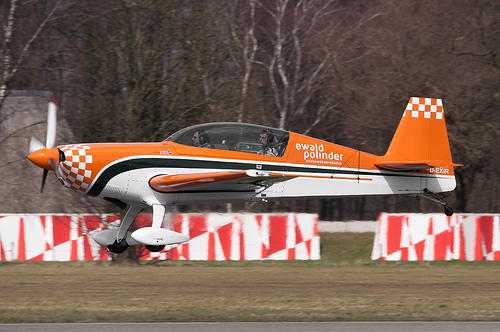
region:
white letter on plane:
[292, 141, 304, 151]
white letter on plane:
[301, 142, 308, 150]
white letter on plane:
[309, 144, 315, 151]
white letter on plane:
[313, 142, 319, 150]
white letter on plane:
[301, 148, 310, 160]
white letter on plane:
[308, 148, 315, 158]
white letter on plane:
[322, 150, 329, 161]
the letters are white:
[295, 142, 335, 158]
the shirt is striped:
[257, 147, 270, 159]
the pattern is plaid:
[67, 142, 94, 199]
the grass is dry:
[63, 249, 412, 329]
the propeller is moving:
[28, 110, 71, 202]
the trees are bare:
[152, 3, 338, 118]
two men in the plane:
[185, 132, 270, 158]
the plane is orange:
[80, 121, 450, 190]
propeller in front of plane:
[22, 94, 70, 201]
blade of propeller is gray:
[39, 92, 62, 145]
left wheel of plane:
[88, 223, 137, 259]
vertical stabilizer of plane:
[380, 83, 453, 161]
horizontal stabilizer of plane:
[374, 151, 465, 180]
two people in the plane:
[181, 123, 278, 157]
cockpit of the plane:
[159, 112, 296, 162]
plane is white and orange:
[13, 70, 463, 255]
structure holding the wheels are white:
[82, 203, 195, 259]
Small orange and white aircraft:
[14, 86, 461, 261]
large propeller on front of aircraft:
[16, 103, 73, 198]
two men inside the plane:
[174, 115, 279, 155]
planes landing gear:
[88, 218, 192, 256]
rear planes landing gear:
[441, 195, 458, 219]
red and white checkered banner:
[3, 207, 498, 264]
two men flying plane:
[21, 86, 470, 242]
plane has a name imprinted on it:
[293, 137, 345, 169]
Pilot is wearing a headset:
[186, 128, 221, 150]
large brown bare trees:
[57, 5, 332, 135]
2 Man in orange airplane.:
[28, 88, 475, 249]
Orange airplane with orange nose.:
[21, 97, 485, 255]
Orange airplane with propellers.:
[22, 91, 479, 252]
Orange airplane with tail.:
[22, 81, 482, 253]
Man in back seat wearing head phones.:
[250, 121, 282, 153]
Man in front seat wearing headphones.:
[186, 120, 216, 155]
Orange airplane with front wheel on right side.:
[27, 85, 487, 250]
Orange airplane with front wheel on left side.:
[30, 94, 467, 251]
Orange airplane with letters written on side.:
[25, 90, 465, 255]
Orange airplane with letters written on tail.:
[25, 92, 467, 249]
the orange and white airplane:
[27, 85, 464, 253]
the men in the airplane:
[190, 126, 279, 156]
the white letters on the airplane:
[295, 141, 344, 165]